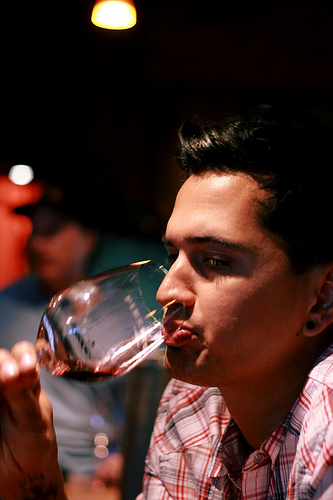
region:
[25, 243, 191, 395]
a nearly empty glass of red wine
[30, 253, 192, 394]
an almost finished glass of red wine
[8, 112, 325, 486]
a man with dark hair drinking a glass of wine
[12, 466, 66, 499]
a small tattoo on the man's right wrist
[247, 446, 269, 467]
the top button of a button-down shirt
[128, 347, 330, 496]
a plaid button-down shirt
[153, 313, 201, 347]
a man's lips taking a sip of wine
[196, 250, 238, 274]
the man's left eye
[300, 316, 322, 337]
a black earring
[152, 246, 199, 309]
the man's nose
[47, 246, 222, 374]
the man is drinking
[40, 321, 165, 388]
the glass is a wine glass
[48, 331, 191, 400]
wine glass has wine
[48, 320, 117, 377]
the wine is red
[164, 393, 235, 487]
man's shirt is plaid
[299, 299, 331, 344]
the earring is black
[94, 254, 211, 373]
wine glass is on man's mouth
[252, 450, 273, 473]
the button is transparent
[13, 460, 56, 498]
man's tattoo on the wrist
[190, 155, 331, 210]
the hair is black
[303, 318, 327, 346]
black ear ring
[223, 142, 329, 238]
black mens hair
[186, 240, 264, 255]
black men eye brow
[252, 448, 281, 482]
clear button on a shirt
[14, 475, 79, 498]
tattoo on mans wrist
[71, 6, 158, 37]
light on the ceiling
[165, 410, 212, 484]
red and white plaid shirt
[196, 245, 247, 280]
a mans brown eye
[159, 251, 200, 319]
a mans nose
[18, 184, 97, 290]
blurry man in back ground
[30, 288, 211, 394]
The man is drinking wine.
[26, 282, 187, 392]
The man has a wine glass in his hand.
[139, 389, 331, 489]
The man is wearing a striped shirt.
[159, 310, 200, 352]
The man has his laps puck out.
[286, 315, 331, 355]
The man has an earring in his left ear.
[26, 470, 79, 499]
The man has a tattoo on his wrist.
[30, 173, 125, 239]
The man is wearing a cap.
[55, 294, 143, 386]
The wine glass has a red substance in it.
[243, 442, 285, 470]
a button is on the collar.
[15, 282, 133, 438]
The man in the back has on a blue shirt.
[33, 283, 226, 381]
The man has a glass toward his mouth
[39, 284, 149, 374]
The glass has wine in it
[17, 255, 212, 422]
A man is holding a wine glass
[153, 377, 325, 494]
The man has on a striped shirt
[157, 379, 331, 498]
The shirt has red, white and blue stripes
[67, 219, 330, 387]
The man is drinking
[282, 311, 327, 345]
The man has an earring in his ear.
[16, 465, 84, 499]
The man has a tattoo on his wrist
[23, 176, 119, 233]
The cap is black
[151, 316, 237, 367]
The man lips are perked